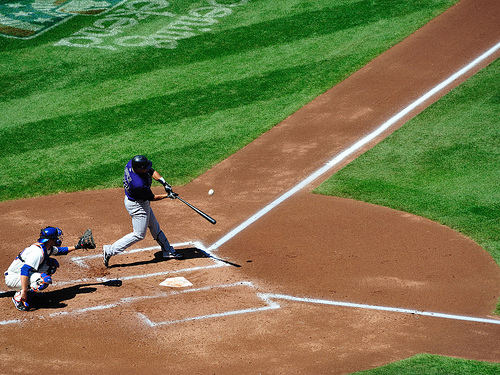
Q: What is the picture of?
A: A baseball game.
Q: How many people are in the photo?
A: Two.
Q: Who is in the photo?
A: A batter and catcher.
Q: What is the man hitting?
A: A baseball.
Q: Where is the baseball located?
A: In the air.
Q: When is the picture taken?
A: During the day.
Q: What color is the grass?
A: Green.